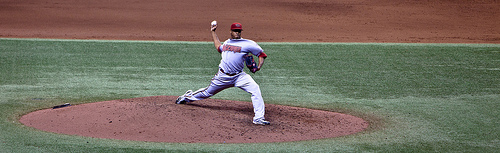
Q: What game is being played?
A: Baseball.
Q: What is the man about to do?
A: Pitch the ball.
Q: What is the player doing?
A: Pitching.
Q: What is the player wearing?
A: Cap.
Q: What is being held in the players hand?
A: Ball.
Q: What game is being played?
A: Baseball.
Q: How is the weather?
A: Clear.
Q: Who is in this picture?
A: A man.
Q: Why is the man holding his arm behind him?
A: Because he is pitching.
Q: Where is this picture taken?
A: A baseball field.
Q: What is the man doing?
A: Playing baseball.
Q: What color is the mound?
A: Brown.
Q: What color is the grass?
A: Green.